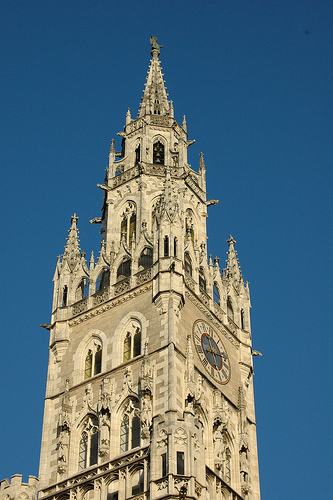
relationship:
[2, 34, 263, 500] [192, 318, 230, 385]
cathedral has a clock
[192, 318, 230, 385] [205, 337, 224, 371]
clock has arms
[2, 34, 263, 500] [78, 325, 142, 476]
cathedral has windows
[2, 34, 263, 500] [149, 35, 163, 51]
cathedral has a statue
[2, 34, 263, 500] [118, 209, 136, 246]
cathedral has two windows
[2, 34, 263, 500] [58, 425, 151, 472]
cathedral has carvings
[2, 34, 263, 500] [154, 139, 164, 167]
cathedral has a small window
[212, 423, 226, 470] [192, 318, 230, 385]
religious statue below clock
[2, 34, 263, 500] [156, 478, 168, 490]
cathedral has a small scripture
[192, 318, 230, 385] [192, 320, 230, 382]
clock has roman numerals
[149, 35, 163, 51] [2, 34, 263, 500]
statue on top of cathedral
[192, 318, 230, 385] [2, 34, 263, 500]
clock on cathedral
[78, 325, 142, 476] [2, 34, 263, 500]
windows are on cathedral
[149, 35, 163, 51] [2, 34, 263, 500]
statue on cathedral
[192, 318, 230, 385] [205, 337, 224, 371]
clock has hands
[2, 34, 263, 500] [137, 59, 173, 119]
cathedral has a roof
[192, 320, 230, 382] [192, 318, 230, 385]
roman numerals are on clock